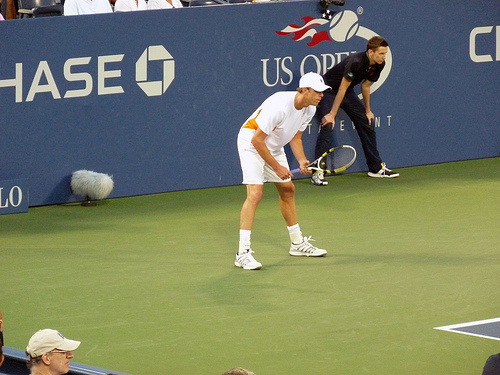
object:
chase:
[1, 43, 191, 105]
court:
[0, 153, 496, 369]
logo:
[259, 8, 395, 135]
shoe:
[289, 235, 328, 256]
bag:
[68, 169, 113, 206]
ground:
[419, 259, 481, 305]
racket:
[291, 145, 357, 174]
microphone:
[331, 49, 358, 89]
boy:
[309, 31, 404, 185]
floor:
[179, 270, 398, 348]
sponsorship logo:
[0, 41, 176, 102]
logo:
[133, 45, 177, 99]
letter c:
[467, 25, 492, 63]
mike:
[70, 168, 116, 207]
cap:
[300, 70, 331, 93]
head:
[363, 35, 386, 63]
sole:
[233, 260, 260, 271]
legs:
[239, 155, 266, 247]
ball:
[328, 11, 359, 44]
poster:
[0, 14, 500, 216]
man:
[233, 72, 327, 271]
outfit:
[236, 88, 317, 186]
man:
[24, 328, 82, 375]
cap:
[27, 328, 80, 358]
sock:
[238, 228, 251, 255]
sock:
[287, 224, 304, 243]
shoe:
[234, 250, 261, 270]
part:
[233, 289, 269, 310]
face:
[370, 47, 390, 66]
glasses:
[46, 347, 72, 357]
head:
[23, 325, 80, 373]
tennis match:
[2, 0, 499, 375]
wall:
[0, 0, 498, 207]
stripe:
[432, 313, 498, 348]